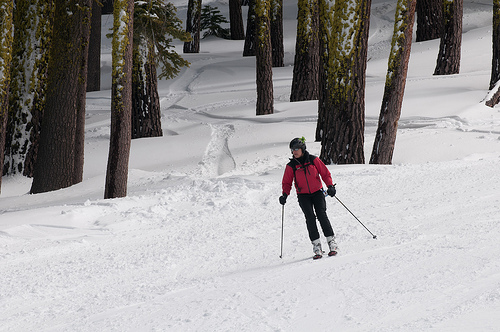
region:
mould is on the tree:
[316, 49, 361, 107]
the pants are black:
[294, 201, 336, 236]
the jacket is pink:
[275, 164, 338, 196]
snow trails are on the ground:
[187, 124, 239, 177]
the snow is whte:
[117, 201, 239, 306]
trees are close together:
[17, 16, 434, 123]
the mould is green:
[325, 28, 358, 82]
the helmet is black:
[284, 138, 308, 148]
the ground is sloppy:
[76, 19, 495, 231]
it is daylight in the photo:
[3, 8, 494, 314]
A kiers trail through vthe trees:
[170, 40, 252, 217]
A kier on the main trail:
[255, 111, 372, 271]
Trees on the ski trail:
[22, 4, 433, 148]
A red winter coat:
[272, 115, 327, 202]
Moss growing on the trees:
[310, 1, 413, 108]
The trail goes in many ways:
[67, 29, 462, 186]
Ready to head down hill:
[255, 140, 396, 260]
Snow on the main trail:
[47, 231, 182, 316]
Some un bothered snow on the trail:
[207, 59, 247, 193]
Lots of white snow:
[50, 221, 419, 305]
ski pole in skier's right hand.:
[274, 222, 286, 258]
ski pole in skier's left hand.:
[352, 196, 381, 243]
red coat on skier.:
[295, 165, 315, 186]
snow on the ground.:
[167, 135, 197, 152]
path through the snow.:
[180, 65, 197, 95]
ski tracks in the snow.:
[396, 180, 477, 237]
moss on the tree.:
[327, 56, 348, 93]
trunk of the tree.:
[39, 90, 69, 165]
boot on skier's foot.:
[328, 233, 339, 260]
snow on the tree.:
[18, 80, 32, 135]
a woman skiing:
[278, 138, 340, 263]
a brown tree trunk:
[105, 2, 135, 196]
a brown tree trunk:
[321, 1, 365, 163]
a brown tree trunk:
[252, 1, 277, 115]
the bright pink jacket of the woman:
[282, 157, 337, 198]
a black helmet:
[287, 135, 304, 150]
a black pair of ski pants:
[292, 185, 332, 237]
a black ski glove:
[277, 193, 289, 203]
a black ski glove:
[326, 183, 337, 198]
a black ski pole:
[276, 197, 288, 259]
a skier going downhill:
[274, 132, 376, 260]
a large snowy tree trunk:
[313, 2, 367, 168]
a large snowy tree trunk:
[29, 0, 89, 190]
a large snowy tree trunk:
[0, 2, 54, 179]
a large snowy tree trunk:
[125, 0, 160, 142]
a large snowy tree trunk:
[290, 0, 328, 102]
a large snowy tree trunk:
[433, 2, 465, 74]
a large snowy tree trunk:
[414, 0, 436, 47]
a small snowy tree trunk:
[365, 0, 421, 167]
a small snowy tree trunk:
[252, 0, 272, 117]